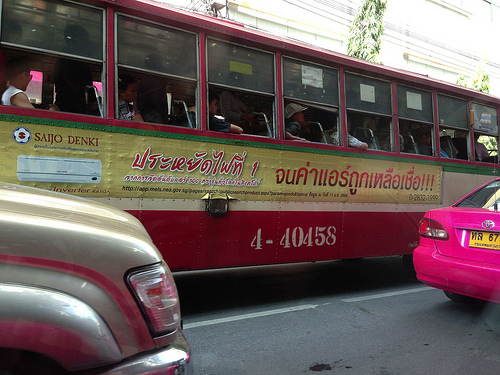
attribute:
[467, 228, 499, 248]
license plate — yellow, black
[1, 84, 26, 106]
shirt — white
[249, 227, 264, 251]
number — white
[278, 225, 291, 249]
number — white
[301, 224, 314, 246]
number — white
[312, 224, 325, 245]
number — white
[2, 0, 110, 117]
window — open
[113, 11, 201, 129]
window — open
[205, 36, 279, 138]
window — open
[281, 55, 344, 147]
window — open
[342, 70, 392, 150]
window — open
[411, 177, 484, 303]
car — pink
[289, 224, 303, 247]
number — white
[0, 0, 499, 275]
red bus — green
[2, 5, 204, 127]
windows — open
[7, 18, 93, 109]
people — looking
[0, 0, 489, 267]
bus — full, yellow, red, white, green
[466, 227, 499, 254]
license plate — yellow, bright yellow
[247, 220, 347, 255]
number — white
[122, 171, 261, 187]
stripe — bright pink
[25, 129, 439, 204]
an ad — multilingual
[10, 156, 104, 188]
logo — silver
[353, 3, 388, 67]
plant — tall, green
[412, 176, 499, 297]
toyota — hot pink, bright pink, pink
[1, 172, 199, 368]
car — beige, bright pink, toyota, gold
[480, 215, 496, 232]
emblem — silver